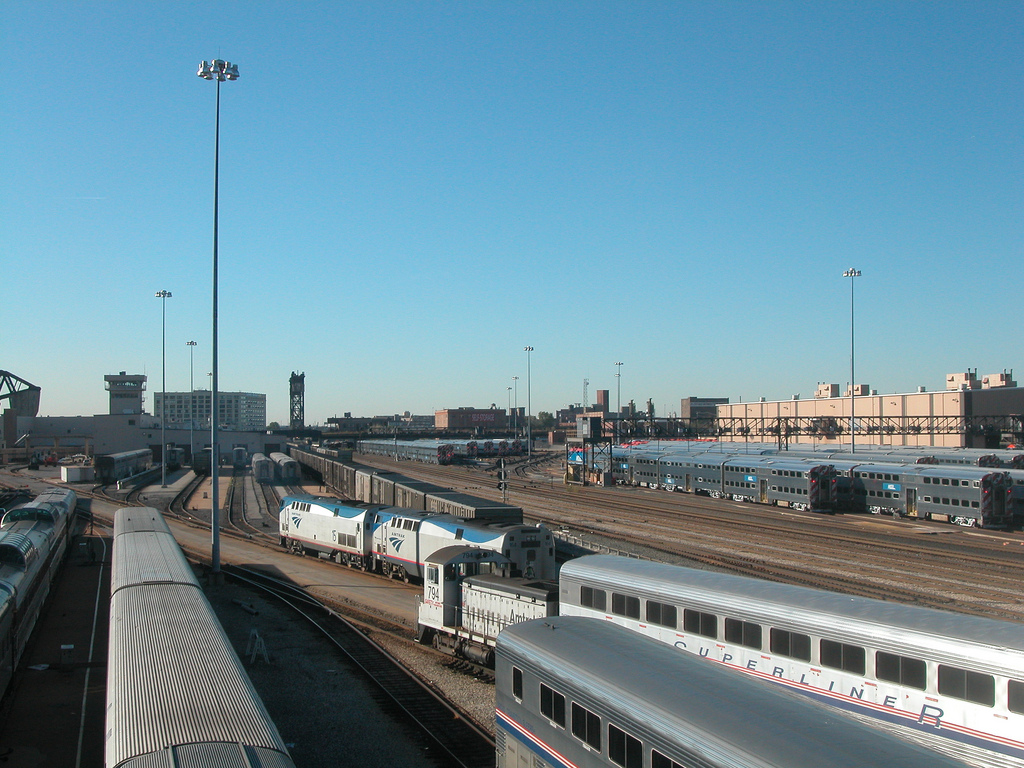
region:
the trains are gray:
[97, 533, 1022, 765]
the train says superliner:
[664, 635, 952, 731]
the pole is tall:
[202, 60, 234, 570]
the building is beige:
[705, 380, 1004, 451]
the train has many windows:
[584, 584, 1022, 720]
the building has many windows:
[151, 392, 263, 431]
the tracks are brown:
[54, 467, 491, 762]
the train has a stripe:
[502, 704, 564, 766]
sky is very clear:
[3, 1, 1019, 444]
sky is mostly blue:
[3, 5, 1022, 470]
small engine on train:
[392, 532, 579, 688]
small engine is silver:
[399, 533, 562, 682]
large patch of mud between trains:
[348, 434, 1022, 632]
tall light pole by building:
[836, 262, 868, 449]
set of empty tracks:
[117, 447, 276, 553]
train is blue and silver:
[241, 467, 558, 613]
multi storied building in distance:
[156, 379, 274, 446]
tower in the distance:
[276, 360, 311, 430]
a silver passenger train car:
[487, 615, 952, 767]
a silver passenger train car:
[106, 582, 293, 766]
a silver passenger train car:
[110, 532, 205, 591]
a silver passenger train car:
[113, 503, 168, 536]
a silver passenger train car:
[657, 451, 727, 499]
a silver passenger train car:
[855, 462, 1017, 538]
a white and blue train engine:
[274, 491, 380, 567]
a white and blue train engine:
[370, 507, 555, 602]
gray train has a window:
[513, 670, 524, 702]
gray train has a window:
[537, 685, 569, 728]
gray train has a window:
[580, 586, 604, 610]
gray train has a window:
[613, 593, 639, 619]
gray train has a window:
[646, 600, 678, 626]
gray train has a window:
[771, 629, 807, 661]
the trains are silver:
[528, 563, 928, 766]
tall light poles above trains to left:
[142, 22, 282, 560]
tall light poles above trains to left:
[120, 34, 263, 584]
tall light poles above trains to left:
[131, 41, 275, 577]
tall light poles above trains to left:
[131, 34, 258, 579]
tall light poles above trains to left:
[147, 40, 275, 598]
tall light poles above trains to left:
[138, 47, 260, 608]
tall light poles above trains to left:
[138, 54, 259, 598]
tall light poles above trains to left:
[148, 35, 247, 580]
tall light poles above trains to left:
[153, 25, 259, 575]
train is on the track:
[103, 506, 291, 762]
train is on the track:
[490, 612, 1019, 762]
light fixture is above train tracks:
[196, 57, 239, 582]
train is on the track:
[280, 488, 553, 584]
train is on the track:
[413, 542, 1018, 761]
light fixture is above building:
[153, 285, 170, 486]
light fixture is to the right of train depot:
[841, 261, 864, 452]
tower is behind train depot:
[285, 368, 304, 430]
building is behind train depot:
[0, 367, 269, 470]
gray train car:
[584, 528, 1018, 747]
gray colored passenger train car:
[620, 445, 837, 522]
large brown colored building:
[721, 394, 959, 445]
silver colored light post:
[189, 41, 250, 381]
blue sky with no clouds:
[369, 23, 481, 161]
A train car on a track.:
[271, 485, 376, 571]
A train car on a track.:
[414, 544, 558, 672]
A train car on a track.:
[482, 618, 973, 764]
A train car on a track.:
[555, 563, 1021, 766]